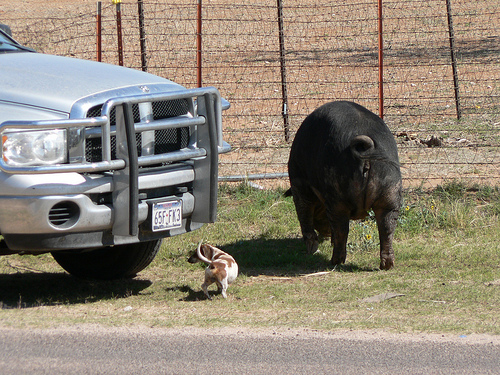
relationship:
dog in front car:
[185, 238, 238, 301] [1, 24, 235, 298]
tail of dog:
[192, 237, 209, 264] [183, 236, 243, 296]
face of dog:
[186, 241, 207, 262] [184, 233, 244, 302]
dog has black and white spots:
[185, 238, 238, 301] [225, 261, 238, 283]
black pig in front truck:
[303, 133, 324, 163] [2, 39, 216, 249]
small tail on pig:
[355, 133, 371, 161] [275, 97, 406, 277]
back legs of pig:
[300, 134, 316, 169] [280, 84, 409, 283]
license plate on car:
[151, 207, 183, 232] [1, 24, 235, 298]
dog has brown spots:
[182, 228, 243, 301] [215, 251, 236, 267]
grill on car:
[2, 89, 235, 174] [1, 24, 235, 298]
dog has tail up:
[185, 238, 238, 301] [188, 234, 215, 267]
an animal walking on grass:
[275, 92, 410, 274] [413, 197, 470, 252]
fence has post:
[8, 4, 498, 192] [273, 0, 291, 144]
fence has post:
[8, 4, 498, 192] [371, 0, 385, 120]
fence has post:
[8, 4, 498, 192] [444, 2, 465, 121]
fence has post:
[8, 4, 498, 192] [195, 3, 203, 85]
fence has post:
[8, 4, 498, 192] [113, 0, 125, 65]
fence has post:
[8, 4, 498, 192] [94, 0, 103, 60]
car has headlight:
[1, 24, 235, 298] [0, 122, 68, 165]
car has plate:
[1, 24, 235, 298] [147, 198, 184, 228]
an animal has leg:
[283, 95, 405, 274] [375, 193, 400, 270]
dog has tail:
[185, 238, 238, 301] [195, 238, 214, 265]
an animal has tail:
[283, 95, 405, 274] [349, 133, 376, 157]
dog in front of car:
[185, 238, 238, 301] [1, 24, 235, 298]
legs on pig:
[332, 212, 355, 269] [275, 97, 406, 277]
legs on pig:
[375, 209, 396, 273] [275, 97, 406, 277]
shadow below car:
[1, 264, 153, 318] [1, 24, 235, 298]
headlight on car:
[0, 122, 68, 165] [1, 24, 235, 298]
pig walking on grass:
[275, 97, 406, 277] [5, 166, 497, 335]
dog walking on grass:
[185, 238, 238, 301] [5, 166, 497, 335]